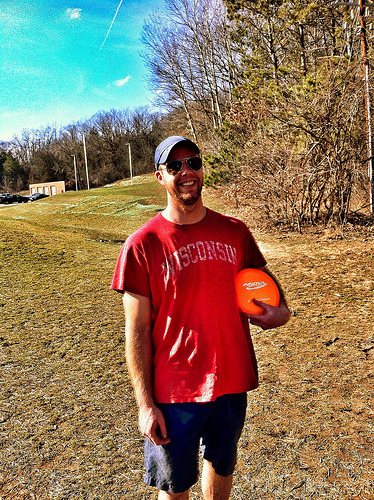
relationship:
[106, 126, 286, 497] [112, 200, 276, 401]
man in shirt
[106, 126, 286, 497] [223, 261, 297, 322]
man has frisbee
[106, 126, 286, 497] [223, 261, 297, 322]
man holding frisbee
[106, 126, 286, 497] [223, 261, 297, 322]
man with frisbee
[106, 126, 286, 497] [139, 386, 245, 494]
man wearing shorts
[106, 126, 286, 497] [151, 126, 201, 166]
man wearing cap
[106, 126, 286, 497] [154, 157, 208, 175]
man has sunglasses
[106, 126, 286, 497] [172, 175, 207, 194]
man has smile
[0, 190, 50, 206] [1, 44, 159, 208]
cars in background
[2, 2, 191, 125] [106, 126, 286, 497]
sky above man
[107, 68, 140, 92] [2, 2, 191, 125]
cloud in sky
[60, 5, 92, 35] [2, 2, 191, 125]
cloud in sky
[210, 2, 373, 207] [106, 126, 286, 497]
woods behind man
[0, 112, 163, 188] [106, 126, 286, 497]
woods behind man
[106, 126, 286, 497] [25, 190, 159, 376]
man in field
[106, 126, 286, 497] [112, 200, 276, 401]
man in t-shirt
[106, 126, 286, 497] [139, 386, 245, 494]
man in shorts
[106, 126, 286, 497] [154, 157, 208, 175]
man wearing sunglasses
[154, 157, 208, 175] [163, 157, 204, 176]
sunglasses over eyes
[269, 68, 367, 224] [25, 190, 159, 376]
bush in field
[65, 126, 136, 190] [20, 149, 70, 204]
poles behind building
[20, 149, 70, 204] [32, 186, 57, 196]
building has doors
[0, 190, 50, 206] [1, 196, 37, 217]
cars in lot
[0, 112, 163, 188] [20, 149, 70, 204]
trees behind building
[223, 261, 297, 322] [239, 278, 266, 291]
frisbee has words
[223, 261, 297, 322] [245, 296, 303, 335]
frisbee in hand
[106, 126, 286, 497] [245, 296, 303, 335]
man has hand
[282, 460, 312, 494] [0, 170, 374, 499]
branch on field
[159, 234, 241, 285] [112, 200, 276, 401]
words on shirt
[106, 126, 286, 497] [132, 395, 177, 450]
man has hand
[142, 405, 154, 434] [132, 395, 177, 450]
veins on hand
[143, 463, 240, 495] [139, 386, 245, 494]
edge of shorts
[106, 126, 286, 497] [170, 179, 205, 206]
man has beard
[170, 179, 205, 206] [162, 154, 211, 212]
beard on face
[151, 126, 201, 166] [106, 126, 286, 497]
cap on man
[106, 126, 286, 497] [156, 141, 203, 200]
man has head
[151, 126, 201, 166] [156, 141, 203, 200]
cap on head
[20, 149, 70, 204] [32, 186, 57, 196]
building with doors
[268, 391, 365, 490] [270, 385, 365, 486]
sticks and dirt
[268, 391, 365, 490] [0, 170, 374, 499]
sticks on field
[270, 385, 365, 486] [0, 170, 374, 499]
dirt on field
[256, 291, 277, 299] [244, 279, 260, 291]
orange and white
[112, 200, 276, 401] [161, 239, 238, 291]
t-shirt says words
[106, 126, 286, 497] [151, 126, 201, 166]
man wearing hat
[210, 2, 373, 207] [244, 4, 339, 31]
trees with leaves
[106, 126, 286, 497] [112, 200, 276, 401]
man wearing shirt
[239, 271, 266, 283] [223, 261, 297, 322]
fluorescent orange frisbee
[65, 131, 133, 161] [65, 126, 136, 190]
light on pole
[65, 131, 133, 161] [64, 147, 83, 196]
light on pole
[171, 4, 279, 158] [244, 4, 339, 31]
tree without leaves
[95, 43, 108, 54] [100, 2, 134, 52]
airplane sky exhaust